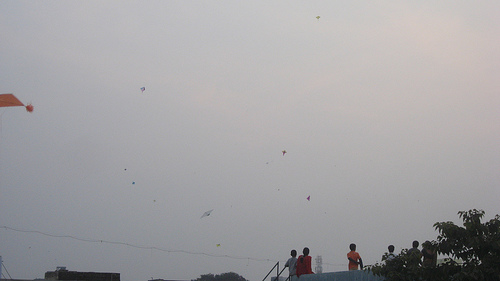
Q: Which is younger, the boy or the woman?
A: The boy is younger than the woman.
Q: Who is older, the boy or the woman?
A: The woman is older than the boy.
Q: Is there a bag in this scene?
A: No, there are no bags.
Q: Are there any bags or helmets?
A: No, there are no bags or helmets.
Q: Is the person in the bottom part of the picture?
A: Yes, the person is in the bottom of the image.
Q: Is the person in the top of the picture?
A: No, the person is in the bottom of the image.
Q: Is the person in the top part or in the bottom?
A: The person is in the bottom of the image.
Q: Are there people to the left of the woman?
A: Yes, there is a person to the left of the woman.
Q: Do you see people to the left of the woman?
A: Yes, there is a person to the left of the woman.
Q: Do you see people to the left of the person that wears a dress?
A: Yes, there is a person to the left of the woman.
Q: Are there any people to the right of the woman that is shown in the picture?
A: No, the person is to the left of the woman.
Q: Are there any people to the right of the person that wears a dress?
A: No, the person is to the left of the woman.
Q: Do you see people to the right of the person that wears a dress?
A: No, the person is to the left of the woman.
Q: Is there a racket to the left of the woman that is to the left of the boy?
A: No, there is a person to the left of the woman.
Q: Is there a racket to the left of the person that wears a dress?
A: No, there is a person to the left of the woman.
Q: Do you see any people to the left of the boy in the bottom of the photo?
A: Yes, there is a person to the left of the boy.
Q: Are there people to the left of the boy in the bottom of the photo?
A: Yes, there is a person to the left of the boy.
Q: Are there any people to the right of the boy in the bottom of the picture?
A: No, the person is to the left of the boy.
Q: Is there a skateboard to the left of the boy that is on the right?
A: No, there is a person to the left of the boy.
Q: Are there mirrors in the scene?
A: No, there are no mirrors.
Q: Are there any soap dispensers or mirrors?
A: No, there are no mirrors or soap dispensers.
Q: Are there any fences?
A: No, there are no fences.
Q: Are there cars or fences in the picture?
A: No, there are no fences or cars.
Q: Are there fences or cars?
A: No, there are no fences or cars.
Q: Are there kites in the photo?
A: Yes, there is a kite.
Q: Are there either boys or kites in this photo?
A: Yes, there is a kite.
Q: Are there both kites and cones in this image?
A: No, there is a kite but no cones.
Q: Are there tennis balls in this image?
A: No, there are no tennis balls.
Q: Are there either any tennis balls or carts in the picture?
A: No, there are no tennis balls or carts.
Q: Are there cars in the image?
A: No, there are no cars.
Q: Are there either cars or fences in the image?
A: No, there are no cars or fences.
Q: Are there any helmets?
A: No, there are no helmets.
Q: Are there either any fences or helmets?
A: No, there are no helmets or fences.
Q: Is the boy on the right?
A: Yes, the boy is on the right of the image.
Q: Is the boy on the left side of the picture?
A: No, the boy is on the right of the image.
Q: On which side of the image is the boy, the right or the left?
A: The boy is on the right of the image.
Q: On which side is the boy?
A: The boy is on the right of the image.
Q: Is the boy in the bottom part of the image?
A: Yes, the boy is in the bottom of the image.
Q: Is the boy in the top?
A: No, the boy is in the bottom of the image.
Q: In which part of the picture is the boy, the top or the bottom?
A: The boy is in the bottom of the image.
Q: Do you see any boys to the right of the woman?
A: Yes, there is a boy to the right of the woman.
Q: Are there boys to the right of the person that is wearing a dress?
A: Yes, there is a boy to the right of the woman.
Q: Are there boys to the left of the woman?
A: No, the boy is to the right of the woman.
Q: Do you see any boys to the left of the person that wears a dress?
A: No, the boy is to the right of the woman.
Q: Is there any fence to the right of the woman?
A: No, there is a boy to the right of the woman.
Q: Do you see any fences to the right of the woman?
A: No, there is a boy to the right of the woman.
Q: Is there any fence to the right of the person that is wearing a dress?
A: No, there is a boy to the right of the woman.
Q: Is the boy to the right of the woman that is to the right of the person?
A: Yes, the boy is to the right of the woman.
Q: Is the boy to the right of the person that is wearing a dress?
A: Yes, the boy is to the right of the woman.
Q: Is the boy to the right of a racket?
A: No, the boy is to the right of the woman.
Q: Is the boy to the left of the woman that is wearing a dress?
A: No, the boy is to the right of the woman.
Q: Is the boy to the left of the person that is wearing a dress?
A: No, the boy is to the right of the woman.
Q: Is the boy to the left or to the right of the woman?
A: The boy is to the right of the woman.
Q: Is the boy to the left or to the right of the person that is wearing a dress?
A: The boy is to the right of the woman.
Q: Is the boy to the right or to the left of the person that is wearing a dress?
A: The boy is to the right of the woman.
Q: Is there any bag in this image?
A: No, there are no bags.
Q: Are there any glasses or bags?
A: No, there are no bags or glasses.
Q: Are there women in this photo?
A: Yes, there is a woman.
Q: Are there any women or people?
A: Yes, there is a woman.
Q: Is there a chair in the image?
A: No, there are no chairs.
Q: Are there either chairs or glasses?
A: No, there are no chairs or glasses.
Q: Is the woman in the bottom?
A: Yes, the woman is in the bottom of the image.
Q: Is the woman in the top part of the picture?
A: No, the woman is in the bottom of the image.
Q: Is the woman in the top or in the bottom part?
A: The woman is in the bottom of the image.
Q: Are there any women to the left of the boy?
A: Yes, there is a woman to the left of the boy.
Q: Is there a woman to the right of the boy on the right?
A: No, the woman is to the left of the boy.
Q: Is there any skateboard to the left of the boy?
A: No, there is a woman to the left of the boy.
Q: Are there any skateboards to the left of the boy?
A: No, there is a woman to the left of the boy.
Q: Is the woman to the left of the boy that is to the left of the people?
A: Yes, the woman is to the left of the boy.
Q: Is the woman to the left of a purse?
A: No, the woman is to the left of the boy.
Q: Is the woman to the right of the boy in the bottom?
A: No, the woman is to the left of the boy.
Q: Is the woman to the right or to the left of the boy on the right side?
A: The woman is to the left of the boy.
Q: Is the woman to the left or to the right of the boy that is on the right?
A: The woman is to the left of the boy.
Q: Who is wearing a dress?
A: The woman is wearing a dress.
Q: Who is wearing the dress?
A: The woman is wearing a dress.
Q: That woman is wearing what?
A: The woman is wearing a dress.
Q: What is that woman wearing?
A: The woman is wearing a dress.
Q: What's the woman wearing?
A: The woman is wearing a dress.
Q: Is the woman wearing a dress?
A: Yes, the woman is wearing a dress.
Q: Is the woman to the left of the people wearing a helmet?
A: No, the woman is wearing a dress.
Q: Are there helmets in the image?
A: No, there are no helmets.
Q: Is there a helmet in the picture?
A: No, there are no helmets.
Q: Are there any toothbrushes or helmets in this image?
A: No, there are no helmets or toothbrushes.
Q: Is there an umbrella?
A: No, there are no umbrellas.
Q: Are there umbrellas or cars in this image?
A: No, there are no umbrellas or cars.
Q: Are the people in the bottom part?
A: Yes, the people are in the bottom of the image.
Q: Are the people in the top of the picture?
A: No, the people are in the bottom of the image.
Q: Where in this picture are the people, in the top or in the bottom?
A: The people are in the bottom of the image.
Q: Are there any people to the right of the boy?
A: Yes, there are people to the right of the boy.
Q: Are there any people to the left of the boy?
A: No, the people are to the right of the boy.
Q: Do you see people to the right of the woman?
A: Yes, there are people to the right of the woman.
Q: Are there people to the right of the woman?
A: Yes, there are people to the right of the woman.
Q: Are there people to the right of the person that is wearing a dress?
A: Yes, there are people to the right of the woman.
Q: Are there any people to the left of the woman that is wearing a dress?
A: No, the people are to the right of the woman.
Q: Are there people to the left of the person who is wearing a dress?
A: No, the people are to the right of the woman.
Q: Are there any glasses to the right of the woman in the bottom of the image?
A: No, there are people to the right of the woman.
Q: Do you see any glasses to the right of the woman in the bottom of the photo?
A: No, there are people to the right of the woman.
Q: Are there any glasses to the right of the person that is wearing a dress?
A: No, there are people to the right of the woman.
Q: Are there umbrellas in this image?
A: No, there are no umbrellas.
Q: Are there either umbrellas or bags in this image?
A: No, there are no umbrellas or bags.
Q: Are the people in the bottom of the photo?
A: Yes, the people are in the bottom of the image.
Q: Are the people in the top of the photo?
A: No, the people are in the bottom of the image.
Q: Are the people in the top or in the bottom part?
A: The people are in the bottom of the image.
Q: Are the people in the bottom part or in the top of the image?
A: The people are in the bottom of the image.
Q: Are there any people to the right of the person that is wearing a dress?
A: Yes, there are people to the right of the woman.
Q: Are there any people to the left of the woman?
A: No, the people are to the right of the woman.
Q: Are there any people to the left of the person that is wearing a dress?
A: No, the people are to the right of the woman.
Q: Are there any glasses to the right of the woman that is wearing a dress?
A: No, there are people to the right of the woman.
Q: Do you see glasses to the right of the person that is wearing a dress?
A: No, there are people to the right of the woman.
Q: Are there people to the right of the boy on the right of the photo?
A: Yes, there are people to the right of the boy.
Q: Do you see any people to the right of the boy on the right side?
A: Yes, there are people to the right of the boy.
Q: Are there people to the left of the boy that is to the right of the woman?
A: No, the people are to the right of the boy.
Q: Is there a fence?
A: No, there are no fences.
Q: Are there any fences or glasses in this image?
A: No, there are no fences or glasses.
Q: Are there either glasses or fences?
A: No, there are no fences or glasses.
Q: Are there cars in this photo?
A: No, there are no cars.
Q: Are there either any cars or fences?
A: No, there are no cars or fences.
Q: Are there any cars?
A: No, there are no cars.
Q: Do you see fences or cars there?
A: No, there are no cars or fences.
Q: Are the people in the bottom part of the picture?
A: Yes, the people are in the bottom of the image.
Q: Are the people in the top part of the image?
A: No, the people are in the bottom of the image.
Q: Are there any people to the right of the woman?
A: Yes, there are people to the right of the woman.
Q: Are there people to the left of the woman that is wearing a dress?
A: No, the people are to the right of the woman.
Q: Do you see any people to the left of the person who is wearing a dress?
A: No, the people are to the right of the woman.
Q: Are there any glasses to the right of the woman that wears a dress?
A: No, there are people to the right of the woman.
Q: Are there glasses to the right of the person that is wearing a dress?
A: No, there are people to the right of the woman.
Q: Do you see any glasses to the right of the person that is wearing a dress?
A: No, there are people to the right of the woman.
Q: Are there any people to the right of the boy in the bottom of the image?
A: Yes, there are people to the right of the boy.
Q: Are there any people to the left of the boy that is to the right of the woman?
A: No, the people are to the right of the boy.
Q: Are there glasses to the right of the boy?
A: No, there are people to the right of the boy.